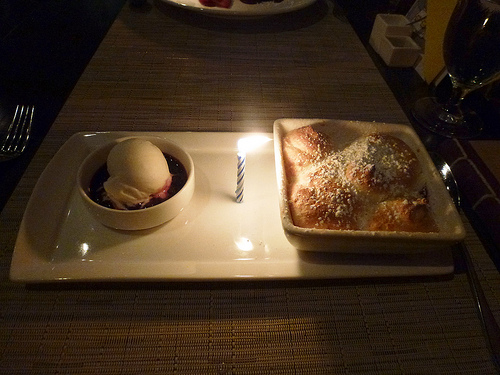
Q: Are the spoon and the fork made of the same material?
A: Yes, both the spoon and the fork are made of metal.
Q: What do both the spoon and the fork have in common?
A: The material, both the spoon and the fork are metallic.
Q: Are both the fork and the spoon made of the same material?
A: Yes, both the fork and the spoon are made of metal.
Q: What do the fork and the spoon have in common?
A: The material, both the fork and the spoon are metallic.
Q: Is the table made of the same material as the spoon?
A: No, the table is made of wood and the spoon is made of metal.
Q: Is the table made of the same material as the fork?
A: No, the table is made of wood and the fork is made of metal.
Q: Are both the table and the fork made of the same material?
A: No, the table is made of wood and the fork is made of metal.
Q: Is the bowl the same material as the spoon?
A: No, the bowl is made of glass and the spoon is made of metal.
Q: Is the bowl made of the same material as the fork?
A: No, the bowl is made of glass and the fork is made of metal.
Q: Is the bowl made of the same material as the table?
A: No, the bowl is made of glass and the table is made of wood.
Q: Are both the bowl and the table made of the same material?
A: No, the bowl is made of glass and the table is made of wood.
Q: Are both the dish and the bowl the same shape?
A: No, the bowl is round and the dish is square.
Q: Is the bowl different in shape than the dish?
A: Yes, the bowl is round and the dish is square.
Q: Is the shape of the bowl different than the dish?
A: Yes, the bowl is round and the dish is square.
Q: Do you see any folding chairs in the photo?
A: No, there are no folding chairs.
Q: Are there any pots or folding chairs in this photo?
A: No, there are no folding chairs or pots.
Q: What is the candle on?
A: The candle is on the food tray.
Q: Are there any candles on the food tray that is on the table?
A: Yes, there is a candle on the food tray.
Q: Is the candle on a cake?
A: No, the candle is on a serving tray.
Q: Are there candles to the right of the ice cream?
A: Yes, there is a candle to the right of the ice cream.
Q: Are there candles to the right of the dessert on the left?
A: Yes, there is a candle to the right of the ice cream.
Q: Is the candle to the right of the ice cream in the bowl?
A: Yes, the candle is to the right of the ice cream.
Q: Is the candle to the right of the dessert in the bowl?
A: Yes, the candle is to the right of the ice cream.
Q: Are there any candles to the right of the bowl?
A: Yes, there is a candle to the right of the bowl.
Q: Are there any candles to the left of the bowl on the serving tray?
A: No, the candle is to the right of the bowl.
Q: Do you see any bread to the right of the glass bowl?
A: No, there is a candle to the right of the bowl.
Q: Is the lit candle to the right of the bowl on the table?
A: Yes, the candle is to the right of the bowl.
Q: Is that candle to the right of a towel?
A: No, the candle is to the right of the bowl.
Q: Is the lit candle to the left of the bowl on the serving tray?
A: No, the candle is to the right of the bowl.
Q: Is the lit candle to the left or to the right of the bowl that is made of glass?
A: The candle is to the right of the bowl.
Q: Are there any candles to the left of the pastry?
A: Yes, there is a candle to the left of the pastry.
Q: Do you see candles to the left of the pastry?
A: Yes, there is a candle to the left of the pastry.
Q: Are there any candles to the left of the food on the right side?
A: Yes, there is a candle to the left of the pastry.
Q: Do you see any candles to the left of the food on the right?
A: Yes, there is a candle to the left of the pastry.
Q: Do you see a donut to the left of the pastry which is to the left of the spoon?
A: No, there is a candle to the left of the pastry.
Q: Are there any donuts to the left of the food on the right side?
A: No, there is a candle to the left of the pastry.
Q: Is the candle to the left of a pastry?
A: Yes, the candle is to the left of a pastry.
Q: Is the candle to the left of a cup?
A: No, the candle is to the left of a pastry.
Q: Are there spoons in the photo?
A: Yes, there is a spoon.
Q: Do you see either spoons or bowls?
A: Yes, there is a spoon.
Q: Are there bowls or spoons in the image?
A: Yes, there is a spoon.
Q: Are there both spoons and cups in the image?
A: No, there is a spoon but no cups.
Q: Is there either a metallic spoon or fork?
A: Yes, there is a metal spoon.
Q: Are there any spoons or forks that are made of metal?
A: Yes, the spoon is made of metal.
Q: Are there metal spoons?
A: Yes, there is a spoon that is made of metal.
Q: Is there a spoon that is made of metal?
A: Yes, there is a spoon that is made of metal.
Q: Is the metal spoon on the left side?
A: No, the spoon is on the right of the image.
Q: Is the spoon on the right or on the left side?
A: The spoon is on the right of the image.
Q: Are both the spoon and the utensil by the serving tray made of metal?
A: Yes, both the spoon and the fork are made of metal.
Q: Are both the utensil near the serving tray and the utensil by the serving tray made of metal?
A: Yes, both the spoon and the fork are made of metal.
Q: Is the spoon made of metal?
A: Yes, the spoon is made of metal.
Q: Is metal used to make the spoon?
A: Yes, the spoon is made of metal.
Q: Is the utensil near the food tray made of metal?
A: Yes, the spoon is made of metal.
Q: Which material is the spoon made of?
A: The spoon is made of metal.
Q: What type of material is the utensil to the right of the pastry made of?
A: The spoon is made of metal.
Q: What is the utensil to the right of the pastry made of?
A: The spoon is made of metal.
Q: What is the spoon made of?
A: The spoon is made of metal.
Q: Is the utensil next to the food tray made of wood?
A: No, the spoon is made of metal.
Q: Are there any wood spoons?
A: No, there is a spoon but it is made of metal.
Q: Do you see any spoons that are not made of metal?
A: No, there is a spoon but it is made of metal.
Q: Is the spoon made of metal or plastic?
A: The spoon is made of metal.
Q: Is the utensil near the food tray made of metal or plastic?
A: The spoon is made of metal.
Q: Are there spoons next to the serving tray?
A: Yes, there is a spoon next to the serving tray.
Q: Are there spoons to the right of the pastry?
A: Yes, there is a spoon to the right of the pastry.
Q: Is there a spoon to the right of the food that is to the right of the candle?
A: Yes, there is a spoon to the right of the pastry.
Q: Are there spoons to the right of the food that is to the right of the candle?
A: Yes, there is a spoon to the right of the pastry.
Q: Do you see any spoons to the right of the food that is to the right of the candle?
A: Yes, there is a spoon to the right of the pastry.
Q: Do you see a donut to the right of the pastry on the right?
A: No, there is a spoon to the right of the pastry.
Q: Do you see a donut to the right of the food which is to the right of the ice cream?
A: No, there is a spoon to the right of the pastry.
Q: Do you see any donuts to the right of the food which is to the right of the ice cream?
A: No, there is a spoon to the right of the pastry.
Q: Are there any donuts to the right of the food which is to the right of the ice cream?
A: No, there is a spoon to the right of the pastry.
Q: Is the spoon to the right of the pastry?
A: Yes, the spoon is to the right of the pastry.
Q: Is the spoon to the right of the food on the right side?
A: Yes, the spoon is to the right of the pastry.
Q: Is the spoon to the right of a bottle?
A: No, the spoon is to the right of the pastry.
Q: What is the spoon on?
A: The spoon is on the table.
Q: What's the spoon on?
A: The spoon is on the table.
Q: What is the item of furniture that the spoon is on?
A: The piece of furniture is a table.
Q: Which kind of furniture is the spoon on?
A: The spoon is on the table.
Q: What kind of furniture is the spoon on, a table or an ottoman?
A: The spoon is on a table.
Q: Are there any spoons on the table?
A: Yes, there is a spoon on the table.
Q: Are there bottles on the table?
A: No, there is a spoon on the table.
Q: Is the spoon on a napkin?
A: No, the spoon is on the table.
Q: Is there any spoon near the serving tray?
A: Yes, there is a spoon near the serving tray.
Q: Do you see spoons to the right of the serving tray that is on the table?
A: Yes, there is a spoon to the right of the food tray.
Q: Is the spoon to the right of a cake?
A: No, the spoon is to the right of the food tray.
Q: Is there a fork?
A: Yes, there is a fork.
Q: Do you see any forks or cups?
A: Yes, there is a fork.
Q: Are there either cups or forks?
A: Yes, there is a fork.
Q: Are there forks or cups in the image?
A: Yes, there is a fork.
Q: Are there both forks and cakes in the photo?
A: No, there is a fork but no cakes.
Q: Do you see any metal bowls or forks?
A: Yes, there is a metal fork.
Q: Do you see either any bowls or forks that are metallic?
A: Yes, the fork is metallic.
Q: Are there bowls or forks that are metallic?
A: Yes, the fork is metallic.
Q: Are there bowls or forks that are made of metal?
A: Yes, the fork is made of metal.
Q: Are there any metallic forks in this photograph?
A: Yes, there is a metal fork.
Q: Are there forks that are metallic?
A: Yes, there is a fork that is metallic.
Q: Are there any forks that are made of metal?
A: Yes, there is a fork that is made of metal.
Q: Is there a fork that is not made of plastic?
A: Yes, there is a fork that is made of metal.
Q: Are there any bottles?
A: No, there are no bottles.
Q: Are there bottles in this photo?
A: No, there are no bottles.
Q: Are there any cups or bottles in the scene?
A: No, there are no bottles or cups.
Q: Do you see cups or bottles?
A: No, there are no bottles or cups.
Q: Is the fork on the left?
A: Yes, the fork is on the left of the image.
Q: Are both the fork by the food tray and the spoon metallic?
A: Yes, both the fork and the spoon are metallic.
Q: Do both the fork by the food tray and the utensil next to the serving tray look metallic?
A: Yes, both the fork and the spoon are metallic.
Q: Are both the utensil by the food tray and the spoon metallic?
A: Yes, both the fork and the spoon are metallic.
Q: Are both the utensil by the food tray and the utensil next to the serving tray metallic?
A: Yes, both the fork and the spoon are metallic.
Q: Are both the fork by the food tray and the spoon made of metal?
A: Yes, both the fork and the spoon are made of metal.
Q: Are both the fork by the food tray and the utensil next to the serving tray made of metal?
A: Yes, both the fork and the spoon are made of metal.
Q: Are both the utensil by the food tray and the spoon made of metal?
A: Yes, both the fork and the spoon are made of metal.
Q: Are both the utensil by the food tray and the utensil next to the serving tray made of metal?
A: Yes, both the fork and the spoon are made of metal.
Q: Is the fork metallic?
A: Yes, the fork is metallic.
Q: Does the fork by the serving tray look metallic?
A: Yes, the fork is metallic.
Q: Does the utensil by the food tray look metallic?
A: Yes, the fork is metallic.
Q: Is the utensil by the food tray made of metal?
A: Yes, the fork is made of metal.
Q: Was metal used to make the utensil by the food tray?
A: Yes, the fork is made of metal.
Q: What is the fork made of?
A: The fork is made of metal.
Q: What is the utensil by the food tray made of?
A: The fork is made of metal.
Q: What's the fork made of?
A: The fork is made of metal.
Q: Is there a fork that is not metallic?
A: No, there is a fork but it is metallic.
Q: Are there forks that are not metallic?
A: No, there is a fork but it is metallic.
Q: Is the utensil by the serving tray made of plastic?
A: No, the fork is made of metal.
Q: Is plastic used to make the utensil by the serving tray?
A: No, the fork is made of metal.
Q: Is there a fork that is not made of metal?
A: No, there is a fork but it is made of metal.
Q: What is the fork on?
A: The fork is on the table.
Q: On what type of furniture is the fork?
A: The fork is on the table.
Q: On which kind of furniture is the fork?
A: The fork is on the table.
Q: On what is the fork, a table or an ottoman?
A: The fork is on a table.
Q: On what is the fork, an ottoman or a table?
A: The fork is on a table.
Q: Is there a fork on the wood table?
A: Yes, there is a fork on the table.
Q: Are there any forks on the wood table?
A: Yes, there is a fork on the table.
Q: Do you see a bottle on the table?
A: No, there is a fork on the table.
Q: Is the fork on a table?
A: Yes, the fork is on a table.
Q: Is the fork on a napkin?
A: No, the fork is on a table.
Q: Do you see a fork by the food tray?
A: Yes, there is a fork by the food tray.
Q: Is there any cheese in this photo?
A: No, there is no cheese.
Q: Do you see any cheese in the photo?
A: No, there is no cheese.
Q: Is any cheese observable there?
A: No, there is no cheese.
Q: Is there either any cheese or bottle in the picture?
A: No, there are no cheese or bottles.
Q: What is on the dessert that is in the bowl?
A: The sauce is on the ice cream.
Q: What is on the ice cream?
A: The sauce is on the ice cream.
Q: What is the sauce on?
A: The sauce is on the ice cream.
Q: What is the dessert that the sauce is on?
A: The dessert is ice cream.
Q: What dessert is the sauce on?
A: The sauce is on the ice cream.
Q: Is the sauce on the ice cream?
A: Yes, the sauce is on the ice cream.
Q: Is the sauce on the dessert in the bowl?
A: Yes, the sauce is on the ice cream.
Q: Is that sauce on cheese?
A: No, the sauce is on the ice cream.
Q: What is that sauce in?
A: The sauce is in the bowl.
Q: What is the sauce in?
A: The sauce is in the bowl.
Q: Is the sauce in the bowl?
A: Yes, the sauce is in the bowl.